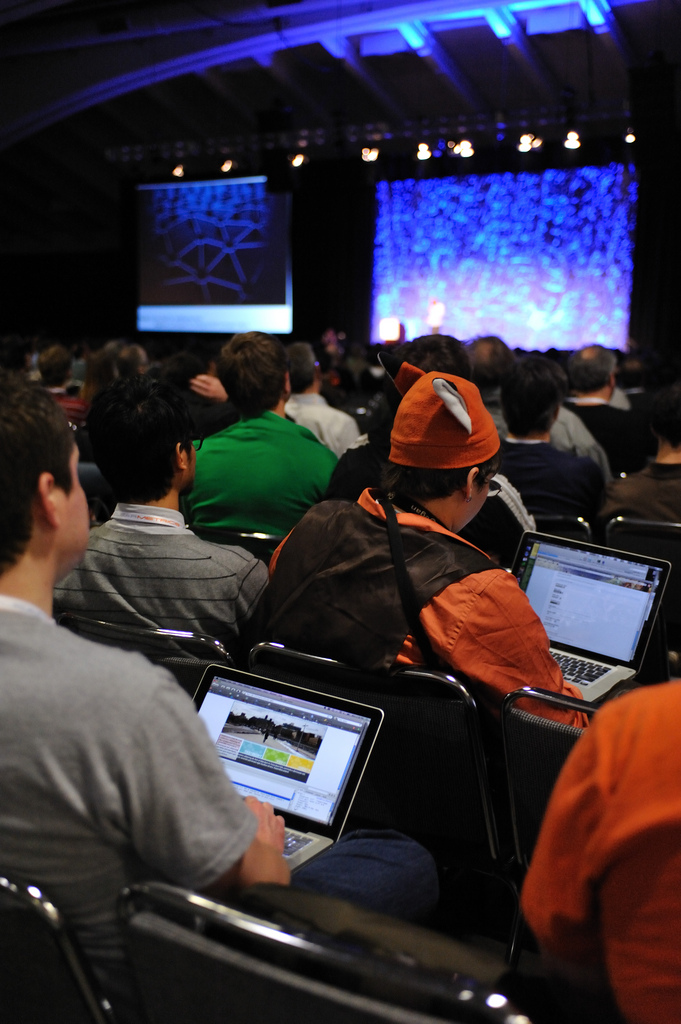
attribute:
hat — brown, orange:
[358, 354, 514, 487]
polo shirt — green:
[207, 419, 328, 544]